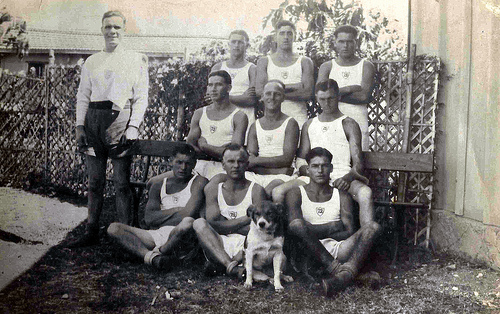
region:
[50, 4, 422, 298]
An old yearbook photo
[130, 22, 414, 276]
The men look to be part of a sports team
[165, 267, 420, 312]
Short grass grows on the ground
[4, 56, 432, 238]
A metal fence behind the men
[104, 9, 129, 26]
The oldest man has short hair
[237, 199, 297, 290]
A dog by all of the people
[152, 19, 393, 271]
Nine men posing with a dog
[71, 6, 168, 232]
A man not posing with the rest of the men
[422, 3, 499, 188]
An old grey wall by the men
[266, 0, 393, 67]
A green tree grows behind the fence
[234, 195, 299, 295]
A cute dog in the middle of a bunch of men posing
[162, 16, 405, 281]
Nine men posing together with a dog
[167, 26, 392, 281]
The men appear to be on some sports team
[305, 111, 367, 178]
The men all wear white tank tops like this one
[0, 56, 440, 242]
A short metal fence behind the men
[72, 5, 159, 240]
The men's teacher stand off to the side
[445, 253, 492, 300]
Small pieces of trash on the ground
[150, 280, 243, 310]
Short grass grows on the ground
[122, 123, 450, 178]
A wooden plank on the fence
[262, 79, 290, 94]
The young man is nearly bald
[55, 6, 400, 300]
a group of men sitting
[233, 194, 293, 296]
a dog in front of the men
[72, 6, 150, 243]
a man beside the group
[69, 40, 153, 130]
he is wearing a collared shirt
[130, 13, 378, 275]
they are wearing sleeveless shirts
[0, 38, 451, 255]
a fence behind the men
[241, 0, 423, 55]
a plant behind the fence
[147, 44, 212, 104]
a plant growing on the fence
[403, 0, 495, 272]
a wall beside the fence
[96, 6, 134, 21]
his hair is light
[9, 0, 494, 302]
an old picture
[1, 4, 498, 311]
picture is black and white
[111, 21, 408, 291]
nine members of team posing for photo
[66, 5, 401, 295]
a coach with players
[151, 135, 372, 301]
a dog in front of players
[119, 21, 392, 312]
players wear white top tanks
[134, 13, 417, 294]
players wear white shorts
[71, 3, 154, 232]
coach has a towel on left shoulder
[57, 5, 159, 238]
coach wears long sleeve shirt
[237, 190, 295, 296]
dog is brown and white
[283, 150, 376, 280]
this is a man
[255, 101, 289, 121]
the man is light skinned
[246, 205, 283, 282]
this is a dog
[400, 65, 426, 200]
this is a fence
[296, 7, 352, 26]
this is a tree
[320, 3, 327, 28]
the leaves are green in color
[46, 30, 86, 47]
this is the roof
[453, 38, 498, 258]
this is a wall